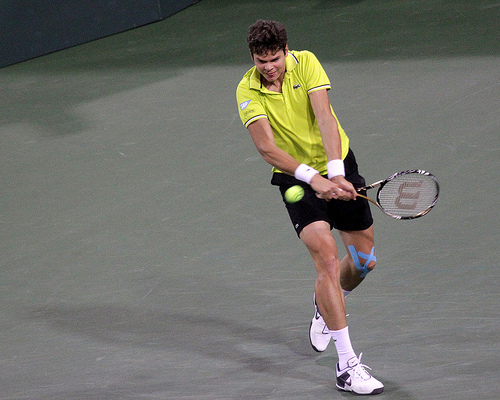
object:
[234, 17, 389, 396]
player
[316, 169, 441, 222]
racket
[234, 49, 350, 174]
shirt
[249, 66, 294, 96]
collar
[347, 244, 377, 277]
stickers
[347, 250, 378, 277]
knee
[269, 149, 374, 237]
shorts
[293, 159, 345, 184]
wristbands